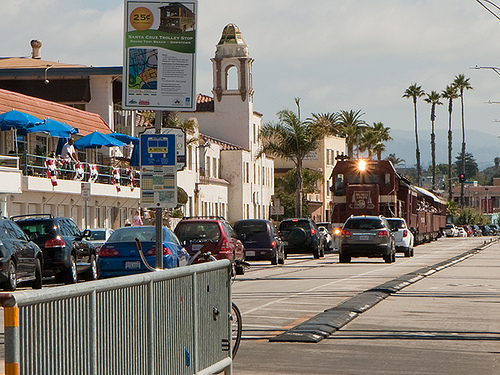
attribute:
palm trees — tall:
[404, 65, 474, 168]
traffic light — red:
[453, 154, 469, 183]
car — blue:
[95, 220, 195, 280]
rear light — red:
[44, 233, 65, 249]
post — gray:
[150, 202, 170, 269]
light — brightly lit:
[348, 154, 371, 172]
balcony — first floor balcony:
[1, 147, 141, 197]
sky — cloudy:
[0, 0, 499, 140]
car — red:
[176, 216, 246, 277]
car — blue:
[96, 224, 191, 277]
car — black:
[233, 217, 286, 267]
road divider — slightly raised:
[268, 239, 498, 341]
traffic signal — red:
[457, 169, 466, 184]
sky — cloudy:
[1, 1, 497, 170]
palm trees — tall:
[402, 75, 474, 201]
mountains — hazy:
[394, 128, 498, 170]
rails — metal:
[1, 256, 233, 373]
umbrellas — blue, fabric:
[1, 109, 138, 151]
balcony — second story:
[2, 160, 142, 196]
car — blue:
[92, 219, 188, 272]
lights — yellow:
[354, 156, 373, 171]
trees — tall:
[406, 72, 468, 203]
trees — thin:
[398, 70, 469, 196]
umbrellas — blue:
[5, 103, 146, 153]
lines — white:
[241, 236, 478, 342]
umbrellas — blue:
[0, 101, 143, 155]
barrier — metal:
[1, 251, 283, 373]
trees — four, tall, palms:
[393, 58, 492, 253]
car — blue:
[87, 203, 207, 313]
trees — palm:
[402, 43, 499, 253]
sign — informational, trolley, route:
[114, 2, 215, 141]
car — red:
[170, 216, 250, 271]